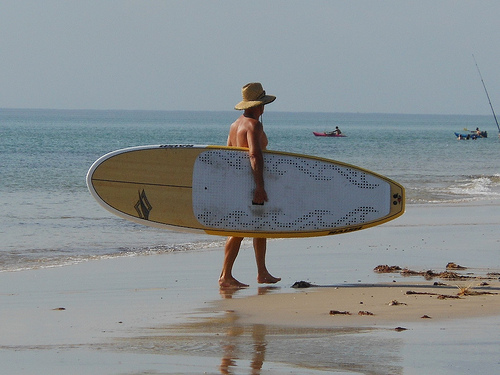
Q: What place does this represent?
A: It represents the beach.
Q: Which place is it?
A: It is a beach.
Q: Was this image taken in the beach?
A: Yes, it was taken in the beach.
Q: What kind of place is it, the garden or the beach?
A: It is the beach.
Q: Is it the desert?
A: No, it is the beach.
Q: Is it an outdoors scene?
A: Yes, it is outdoors.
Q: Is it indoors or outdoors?
A: It is outdoors.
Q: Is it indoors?
A: No, it is outdoors.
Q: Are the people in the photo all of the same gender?
A: No, they are both male and female.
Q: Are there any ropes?
A: No, there are no ropes.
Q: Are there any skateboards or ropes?
A: No, there are no ropes or skateboards.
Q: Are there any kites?
A: No, there are no kites.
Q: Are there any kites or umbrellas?
A: No, there are no kites or umbrellas.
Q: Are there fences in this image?
A: No, there are no fences.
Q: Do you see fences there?
A: No, there are no fences.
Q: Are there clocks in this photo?
A: No, there are no clocks.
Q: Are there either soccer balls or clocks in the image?
A: No, there are no clocks or soccer balls.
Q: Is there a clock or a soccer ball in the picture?
A: No, there are no clocks or soccer balls.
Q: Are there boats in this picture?
A: Yes, there is a boat.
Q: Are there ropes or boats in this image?
A: Yes, there is a boat.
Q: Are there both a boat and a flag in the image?
A: No, there is a boat but no flags.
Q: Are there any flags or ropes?
A: No, there are no ropes or flags.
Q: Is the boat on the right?
A: Yes, the boat is on the right of the image.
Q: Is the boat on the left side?
A: No, the boat is on the right of the image.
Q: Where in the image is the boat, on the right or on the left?
A: The boat is on the right of the image.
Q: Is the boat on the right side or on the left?
A: The boat is on the right of the image.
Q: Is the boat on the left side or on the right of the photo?
A: The boat is on the right of the image.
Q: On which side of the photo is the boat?
A: The boat is on the right of the image.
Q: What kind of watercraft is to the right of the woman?
A: The watercraft is a boat.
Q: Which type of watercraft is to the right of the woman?
A: The watercraft is a boat.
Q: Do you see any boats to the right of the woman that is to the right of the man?
A: Yes, there is a boat to the right of the woman.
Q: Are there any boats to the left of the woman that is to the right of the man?
A: No, the boat is to the right of the woman.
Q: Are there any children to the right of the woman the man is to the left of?
A: No, there is a boat to the right of the woman.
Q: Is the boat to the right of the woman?
A: Yes, the boat is to the right of the woman.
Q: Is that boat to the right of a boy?
A: No, the boat is to the right of the woman.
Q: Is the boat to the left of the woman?
A: No, the boat is to the right of the woman.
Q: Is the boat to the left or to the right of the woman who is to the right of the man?
A: The boat is to the right of the woman.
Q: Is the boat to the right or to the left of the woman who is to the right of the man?
A: The boat is to the right of the woman.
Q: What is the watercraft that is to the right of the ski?
A: The watercraft is a boat.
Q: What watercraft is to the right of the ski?
A: The watercraft is a boat.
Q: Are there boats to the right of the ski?
A: Yes, there is a boat to the right of the ski.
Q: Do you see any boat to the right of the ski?
A: Yes, there is a boat to the right of the ski.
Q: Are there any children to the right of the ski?
A: No, there is a boat to the right of the ski.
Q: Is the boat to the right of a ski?
A: Yes, the boat is to the right of a ski.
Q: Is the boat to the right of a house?
A: No, the boat is to the right of a ski.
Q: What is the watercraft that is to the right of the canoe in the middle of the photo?
A: The watercraft is a boat.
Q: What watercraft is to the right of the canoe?
A: The watercraft is a boat.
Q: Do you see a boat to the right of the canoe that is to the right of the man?
A: Yes, there is a boat to the right of the kayak.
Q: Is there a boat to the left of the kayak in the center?
A: No, the boat is to the right of the canoe.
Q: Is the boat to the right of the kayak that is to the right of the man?
A: Yes, the boat is to the right of the kayak.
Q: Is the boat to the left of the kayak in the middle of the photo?
A: No, the boat is to the right of the kayak.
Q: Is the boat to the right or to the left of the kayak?
A: The boat is to the right of the kayak.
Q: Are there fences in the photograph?
A: No, there are no fences.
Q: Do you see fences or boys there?
A: No, there are no fences or boys.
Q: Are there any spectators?
A: No, there are no spectators.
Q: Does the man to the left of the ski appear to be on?
A: Yes, the man is on.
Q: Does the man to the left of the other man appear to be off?
A: No, the man is on.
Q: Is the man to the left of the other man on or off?
A: The man is on.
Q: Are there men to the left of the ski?
A: Yes, there is a man to the left of the ski.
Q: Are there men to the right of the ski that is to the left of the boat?
A: No, the man is to the left of the ski.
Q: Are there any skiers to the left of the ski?
A: No, there is a man to the left of the ski.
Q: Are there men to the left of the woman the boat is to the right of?
A: Yes, there is a man to the left of the woman.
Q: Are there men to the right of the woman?
A: No, the man is to the left of the woman.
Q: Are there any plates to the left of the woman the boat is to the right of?
A: No, there is a man to the left of the woman.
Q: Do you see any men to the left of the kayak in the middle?
A: Yes, there is a man to the left of the canoe.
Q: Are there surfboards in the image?
A: Yes, there is a surfboard.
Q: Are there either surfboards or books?
A: Yes, there is a surfboard.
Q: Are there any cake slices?
A: No, there are no cake slices.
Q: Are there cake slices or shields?
A: No, there are no cake slices or shields.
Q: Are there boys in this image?
A: No, there are no boys.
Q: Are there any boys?
A: No, there are no boys.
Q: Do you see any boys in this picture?
A: No, there are no boys.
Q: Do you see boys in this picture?
A: No, there are no boys.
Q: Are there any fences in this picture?
A: No, there are no fences.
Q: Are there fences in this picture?
A: No, there are no fences.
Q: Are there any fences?
A: No, there are no fences.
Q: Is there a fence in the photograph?
A: No, there are no fences.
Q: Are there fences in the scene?
A: No, there are no fences.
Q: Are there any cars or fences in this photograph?
A: No, there are no fences or cars.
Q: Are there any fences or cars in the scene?
A: No, there are no fences or cars.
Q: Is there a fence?
A: No, there are no fences.